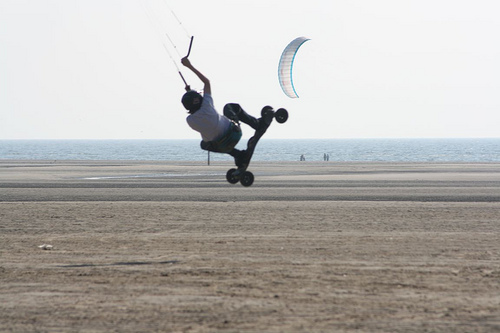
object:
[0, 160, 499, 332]
ground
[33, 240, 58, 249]
rock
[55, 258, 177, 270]
shadow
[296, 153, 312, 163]
people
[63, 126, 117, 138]
surface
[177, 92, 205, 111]
helmet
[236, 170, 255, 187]
wheels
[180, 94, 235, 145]
shirt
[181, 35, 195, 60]
pole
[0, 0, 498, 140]
sky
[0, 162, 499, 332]
sand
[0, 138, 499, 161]
ocean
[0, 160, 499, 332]
beach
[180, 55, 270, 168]
man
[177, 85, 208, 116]
head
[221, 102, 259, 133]
leg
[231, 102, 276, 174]
skateboard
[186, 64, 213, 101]
arm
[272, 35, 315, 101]
kite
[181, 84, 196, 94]
hand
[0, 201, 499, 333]
terrain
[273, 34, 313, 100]
parasail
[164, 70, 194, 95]
handles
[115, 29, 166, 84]
air